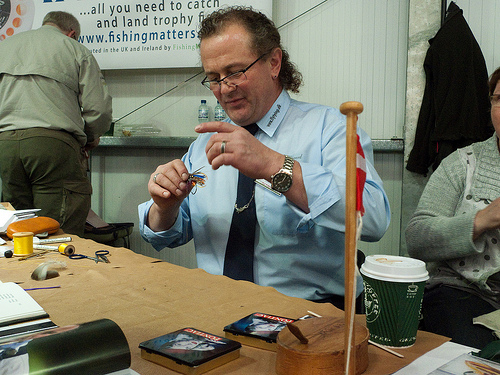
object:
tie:
[221, 124, 258, 284]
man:
[130, 5, 395, 313]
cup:
[358, 253, 430, 350]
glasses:
[200, 49, 286, 91]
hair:
[196, 2, 306, 95]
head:
[192, 3, 306, 127]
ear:
[268, 47, 283, 81]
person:
[418, 47, 500, 276]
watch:
[270, 155, 297, 194]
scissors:
[68, 249, 115, 265]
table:
[0, 204, 500, 375]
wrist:
[259, 148, 290, 179]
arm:
[270, 111, 394, 243]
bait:
[184, 171, 209, 196]